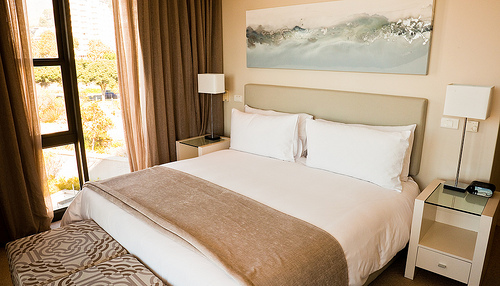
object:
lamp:
[196, 72, 226, 142]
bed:
[59, 83, 429, 285]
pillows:
[301, 115, 412, 193]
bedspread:
[78, 165, 348, 285]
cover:
[58, 149, 421, 285]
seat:
[3, 219, 166, 286]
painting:
[243, 0, 436, 76]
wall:
[221, 0, 499, 195]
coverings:
[112, 0, 224, 173]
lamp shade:
[195, 73, 228, 95]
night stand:
[173, 135, 229, 160]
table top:
[175, 134, 230, 148]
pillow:
[225, 106, 300, 163]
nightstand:
[402, 179, 499, 285]